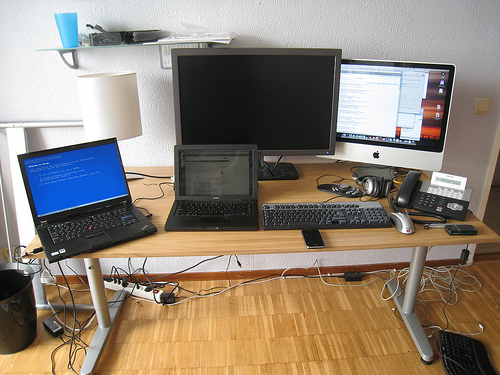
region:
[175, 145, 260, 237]
a small black notebook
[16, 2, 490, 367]
an office space with many computers and laptops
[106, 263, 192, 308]
a power strip with many wires plugged in it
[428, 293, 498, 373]
a keyboard laying on the wooden floor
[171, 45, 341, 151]
a black computer monitor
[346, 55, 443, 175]
a white computer monitor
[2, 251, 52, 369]
a brown paper basket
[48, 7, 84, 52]
a blue plastic glass on the shelf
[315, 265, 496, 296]
a bunch of wires on the floor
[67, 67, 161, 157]
a lamp with white lampshade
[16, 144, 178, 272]
Laptop on a desk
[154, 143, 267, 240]
Small computer on a desk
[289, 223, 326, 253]
Phone on a desk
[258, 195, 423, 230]
Keyboard on a desk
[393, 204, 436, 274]
Mouse on a desk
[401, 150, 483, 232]
Phone on a desk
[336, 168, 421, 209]
Headphones on a desk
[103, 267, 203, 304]
Outlet with cords under a desk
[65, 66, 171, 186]
Lamp on a desk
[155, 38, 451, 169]
Computer monitors on a desk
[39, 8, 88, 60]
Light blue cup sitting on shelf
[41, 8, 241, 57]
Shelf on wall holding various items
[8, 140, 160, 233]
Black laptop with blue screen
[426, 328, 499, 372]
Black keyboard on wooden floor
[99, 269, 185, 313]
Surge protector connected to numerous plugs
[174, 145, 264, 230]
Black laptop with dim screen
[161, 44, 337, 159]
Black monitor with black screen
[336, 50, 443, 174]
Apple monitor with programs bring displayed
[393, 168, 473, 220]
Black, white, and gray telephone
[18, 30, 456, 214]
An assortment of computer monitors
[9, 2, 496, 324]
a desk with 4 computers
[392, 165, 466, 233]
a phone for business use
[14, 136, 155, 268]
a lenovo laptop rebooting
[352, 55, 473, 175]
a mac thunderbolt display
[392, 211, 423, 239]
a wireless logitech mouse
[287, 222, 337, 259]
an apple iphone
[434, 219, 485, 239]
a small video recording device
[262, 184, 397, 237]
a keyboard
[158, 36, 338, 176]
a very large monitor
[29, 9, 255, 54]
a shelf with a glass and paper on it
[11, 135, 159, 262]
Thinkpad on the corner of the desk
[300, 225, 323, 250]
Cell phone in front of the keyboard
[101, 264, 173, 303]
Power strip on the leg of the desk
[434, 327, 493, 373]
Keyboard on the floor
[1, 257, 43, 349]
Black trash can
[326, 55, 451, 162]
Apple computer monitor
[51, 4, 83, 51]
Blue cup on a shelf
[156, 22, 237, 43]
Papers on a shelf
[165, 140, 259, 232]
Laptop in the middle of the desk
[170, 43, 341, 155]
Large blank computer monitor